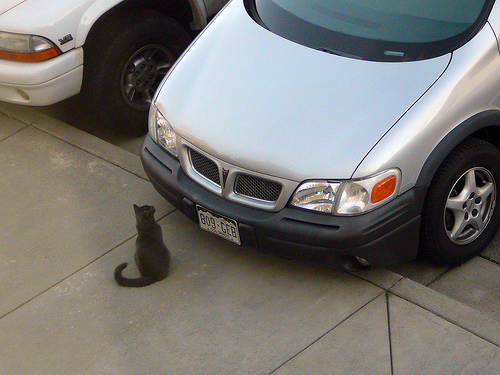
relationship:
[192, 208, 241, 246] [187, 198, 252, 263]
809 geb on license plate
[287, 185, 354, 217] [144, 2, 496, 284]
headlight of van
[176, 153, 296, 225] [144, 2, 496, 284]
grill of van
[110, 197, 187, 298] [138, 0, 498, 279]
cat looking at automobile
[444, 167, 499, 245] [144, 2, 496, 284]
rim on van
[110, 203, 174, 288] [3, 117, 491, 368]
cat on sidewalk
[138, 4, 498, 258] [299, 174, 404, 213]
automobile left headlights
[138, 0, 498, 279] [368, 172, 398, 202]
automobile has turn signal